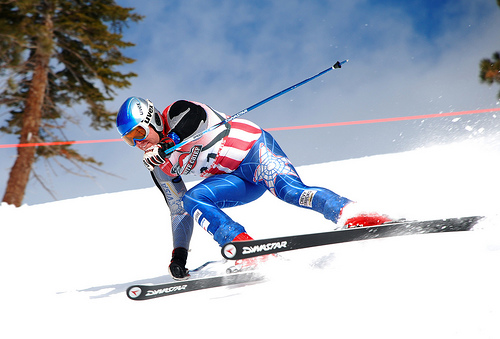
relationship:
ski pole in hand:
[157, 52, 348, 163] [138, 134, 176, 173]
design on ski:
[221, 243, 239, 260] [113, 253, 471, 308]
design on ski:
[121, 280, 146, 300] [214, 211, 489, 263]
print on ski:
[238, 239, 292, 255] [218, 210, 488, 258]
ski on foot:
[218, 210, 488, 258] [336, 204, 397, 236]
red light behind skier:
[1, 102, 498, 152] [113, 57, 482, 302]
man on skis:
[114, 93, 406, 283] [124, 212, 499, 304]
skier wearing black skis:
[114, 95, 399, 279] [127, 209, 479, 308]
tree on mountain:
[25, 26, 120, 118] [35, 181, 459, 333]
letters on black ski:
[145, 283, 190, 295] [222, 217, 475, 260]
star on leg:
[252, 140, 299, 197] [237, 132, 392, 228]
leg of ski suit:
[237, 132, 392, 228] [142, 95, 409, 259]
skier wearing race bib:
[114, 95, 399, 279] [191, 146, 223, 177]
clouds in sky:
[248, 12, 297, 58] [242, 13, 355, 31]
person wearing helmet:
[72, 86, 374, 286] [86, 89, 197, 156]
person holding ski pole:
[100, 92, 382, 302] [157, 52, 348, 163]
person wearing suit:
[114, 95, 408, 281] [113, 91, 401, 276]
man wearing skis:
[111, 88, 391, 257] [128, 203, 468, 297]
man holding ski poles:
[66, 60, 413, 266] [176, 59, 350, 276]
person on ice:
[114, 95, 408, 281] [0, 132, 500, 336]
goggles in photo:
[119, 126, 159, 151] [6, 4, 495, 334]